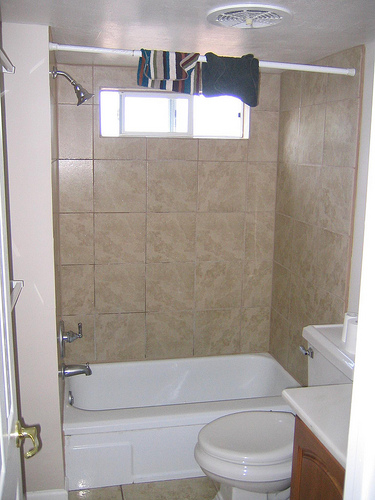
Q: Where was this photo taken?
A: In a bathroom.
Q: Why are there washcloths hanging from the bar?
A: To dry.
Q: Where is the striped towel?
A: Hanging from the shower curtain rod.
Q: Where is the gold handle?
A: On the bathroom door.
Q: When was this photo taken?
A: During the daytime.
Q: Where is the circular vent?
A: In the ceiling.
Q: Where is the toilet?
A: Beside the bathtub.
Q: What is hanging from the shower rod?
A: Washcloths.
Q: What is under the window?
A: Tiles.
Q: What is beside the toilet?
A: A sink.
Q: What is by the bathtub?
A: A toilet.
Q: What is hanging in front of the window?
A: A couple of washcloths.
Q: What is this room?
A: It is a bathroom .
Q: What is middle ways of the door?
A: A door knob.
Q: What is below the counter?
A: Wooden door.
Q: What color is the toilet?
A: White.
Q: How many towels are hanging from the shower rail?
A: 2.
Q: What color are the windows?
A: White.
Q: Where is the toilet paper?
A: On the toilet.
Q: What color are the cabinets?
A: Brown.